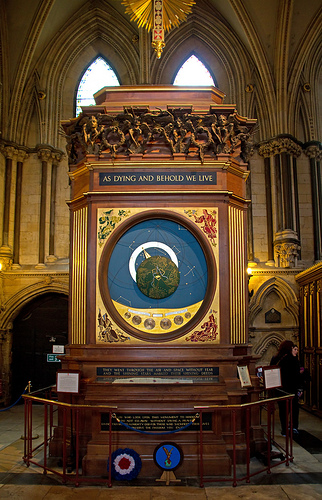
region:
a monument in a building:
[25, 50, 293, 498]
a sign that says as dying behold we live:
[98, 161, 217, 199]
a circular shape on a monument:
[96, 205, 218, 343]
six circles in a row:
[109, 299, 207, 335]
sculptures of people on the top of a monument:
[74, 111, 243, 158]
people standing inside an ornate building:
[265, 327, 311, 448]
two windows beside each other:
[28, 16, 268, 120]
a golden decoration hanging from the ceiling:
[99, 0, 210, 61]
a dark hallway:
[0, 287, 72, 411]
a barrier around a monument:
[17, 385, 297, 485]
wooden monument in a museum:
[19, 85, 297, 486]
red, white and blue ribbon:
[107, 447, 141, 482]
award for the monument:
[152, 439, 182, 485]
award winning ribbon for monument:
[107, 447, 143, 482]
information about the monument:
[262, 365, 283, 391]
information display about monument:
[54, 368, 80, 396]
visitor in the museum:
[276, 341, 306, 437]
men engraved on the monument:
[53, 103, 253, 159]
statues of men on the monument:
[58, 105, 257, 163]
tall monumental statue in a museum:
[6, 4, 313, 494]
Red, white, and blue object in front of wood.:
[110, 448, 151, 498]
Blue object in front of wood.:
[148, 443, 192, 492]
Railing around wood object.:
[23, 379, 114, 468]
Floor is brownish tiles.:
[6, 470, 42, 497]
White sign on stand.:
[47, 359, 112, 433]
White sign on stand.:
[254, 356, 280, 411]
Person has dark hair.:
[277, 333, 311, 380]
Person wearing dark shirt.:
[264, 353, 312, 394]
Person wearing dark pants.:
[266, 396, 304, 429]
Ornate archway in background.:
[11, 281, 77, 351]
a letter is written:
[101, 172, 107, 183]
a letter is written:
[106, 173, 111, 179]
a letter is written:
[113, 173, 120, 181]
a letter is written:
[117, 172, 124, 183]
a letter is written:
[123, 173, 130, 181]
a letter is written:
[130, 172, 136, 182]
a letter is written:
[137, 173, 144, 182]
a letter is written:
[147, 173, 154, 181]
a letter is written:
[176, 171, 183, 180]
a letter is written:
[185, 171, 191, 182]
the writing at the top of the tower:
[98, 170, 219, 188]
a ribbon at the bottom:
[105, 445, 142, 483]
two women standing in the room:
[267, 339, 302, 432]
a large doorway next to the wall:
[14, 294, 65, 399]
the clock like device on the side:
[100, 207, 214, 340]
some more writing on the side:
[95, 365, 221, 376]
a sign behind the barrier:
[56, 368, 82, 400]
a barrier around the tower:
[23, 381, 299, 489]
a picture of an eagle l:
[157, 444, 176, 467]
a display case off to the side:
[291, 255, 320, 412]